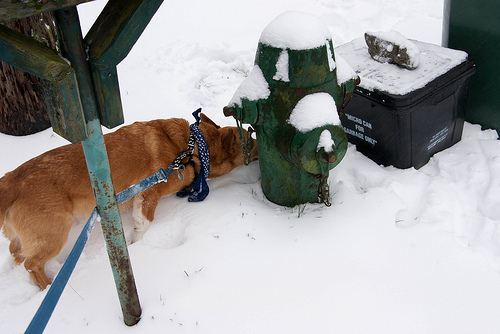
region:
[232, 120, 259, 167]
chain on a green hydrant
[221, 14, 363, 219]
green colored fire hydrant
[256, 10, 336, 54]
snow on top of a green hydrant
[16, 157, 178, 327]
dog's blue colored leash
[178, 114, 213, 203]
dog's blue and white collar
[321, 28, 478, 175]
black box near hydrant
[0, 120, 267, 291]
brown dog in the snow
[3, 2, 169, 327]
green metal posts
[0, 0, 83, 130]
brown wood tree stump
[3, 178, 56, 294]
back legs of a dog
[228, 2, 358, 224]
green fire hydrant covered in snow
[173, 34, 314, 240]
brown dog sniffing a fire hydrant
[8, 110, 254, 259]
brown dog wearing a blue leash in the snow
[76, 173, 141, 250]
blue leash wrapped around a metal pole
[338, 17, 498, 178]
black plastic box in the snow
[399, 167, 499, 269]
footprints in snow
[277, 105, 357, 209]
fire hose attachment site on a fire hydrant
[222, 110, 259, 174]
cover chain on fire hydrant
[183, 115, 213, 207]
blue bandana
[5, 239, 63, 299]
dog paws buried in snow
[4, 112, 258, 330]
brown dog on a blue leash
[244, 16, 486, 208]
recycling bin in the snow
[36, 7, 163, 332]
rusted blue metal pole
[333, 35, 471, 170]
rock on top of recycling bin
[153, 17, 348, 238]
dog smelling fire hydrant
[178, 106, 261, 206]
blue bandana on dogs neck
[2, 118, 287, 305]
dog standing behind blue pole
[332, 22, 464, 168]
white print on black bin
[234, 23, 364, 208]
a fire hydrant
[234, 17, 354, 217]
a green fire hydrant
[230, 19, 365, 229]
a fire hydrant in the snow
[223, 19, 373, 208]
a green fire hydrant in the snow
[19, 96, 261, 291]
a dog sniffs the fire hydrant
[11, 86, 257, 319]
the dog is on a leach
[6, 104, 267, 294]
the dog is in the snow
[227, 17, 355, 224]
snow is on top of the hydrant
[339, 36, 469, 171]
a black container is on the ground next to the hydrant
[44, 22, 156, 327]
a metal pole is stuck in the snow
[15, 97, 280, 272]
A dog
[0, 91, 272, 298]
A dog with a blue collar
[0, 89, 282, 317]
A dog on a blue leash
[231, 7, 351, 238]
A green fire hydrant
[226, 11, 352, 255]
A fire hydrant covered in snow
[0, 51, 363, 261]
A dog sniffing a fire hydrant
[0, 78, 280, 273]
A dog with golden fur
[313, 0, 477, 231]
A black trash can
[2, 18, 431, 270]
A dog out for a walk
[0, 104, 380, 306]
A dog in the snow